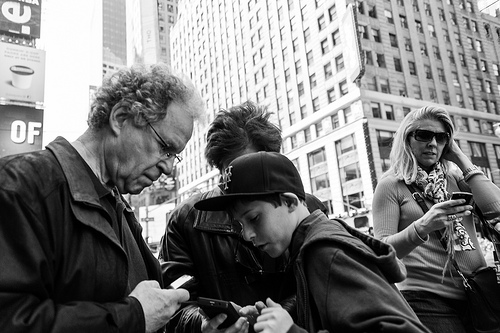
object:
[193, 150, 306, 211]
baseball hat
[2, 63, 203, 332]
man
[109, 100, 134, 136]
ear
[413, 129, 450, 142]
sunglasses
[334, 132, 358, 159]
window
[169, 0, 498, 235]
building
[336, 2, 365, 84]
sign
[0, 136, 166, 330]
jacket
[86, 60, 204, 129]
hair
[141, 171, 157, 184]
mouth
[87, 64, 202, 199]
head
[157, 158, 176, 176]
nose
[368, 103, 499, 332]
people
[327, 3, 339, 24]
window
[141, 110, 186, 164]
glasses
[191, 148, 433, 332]
boy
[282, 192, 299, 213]
ear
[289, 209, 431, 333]
sweatshirt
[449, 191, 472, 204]
cell phone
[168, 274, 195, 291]
phone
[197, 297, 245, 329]
phone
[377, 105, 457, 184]
hair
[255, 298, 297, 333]
hands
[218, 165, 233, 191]
logo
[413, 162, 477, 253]
scarf